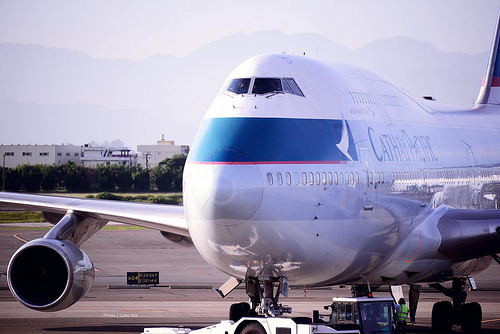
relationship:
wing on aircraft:
[0, 189, 187, 254] [1, 42, 496, 319]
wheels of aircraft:
[420, 296, 486, 329] [1, 42, 496, 319]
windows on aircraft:
[230, 73, 303, 96] [1, 42, 496, 319]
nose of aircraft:
[188, 163, 248, 202] [1, 42, 496, 319]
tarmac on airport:
[8, 308, 212, 317] [1, 42, 496, 319]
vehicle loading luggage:
[323, 291, 397, 332] [317, 303, 339, 322]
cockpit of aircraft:
[230, 73, 303, 96] [1, 42, 496, 319]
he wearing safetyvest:
[396, 296, 412, 331] [396, 304, 407, 320]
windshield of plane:
[230, 73, 303, 96] [1, 42, 496, 319]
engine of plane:
[4, 237, 94, 314] [1, 42, 496, 319]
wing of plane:
[0, 189, 187, 254] [1, 42, 496, 319]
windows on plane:
[342, 91, 407, 110] [1, 42, 496, 319]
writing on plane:
[368, 123, 440, 169] [1, 42, 496, 319]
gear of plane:
[231, 283, 295, 317] [1, 42, 496, 319]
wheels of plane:
[420, 296, 486, 329] [1, 42, 496, 319]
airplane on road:
[1, 42, 496, 319] [0, 222, 500, 333]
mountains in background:
[2, 34, 181, 88] [0, 1, 466, 56]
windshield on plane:
[230, 73, 303, 96] [1, 42, 496, 319]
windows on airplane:
[230, 73, 303, 96] [1, 42, 496, 319]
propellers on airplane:
[16, 238, 65, 305] [1, 42, 496, 319]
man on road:
[394, 298, 409, 332] [0, 222, 500, 333]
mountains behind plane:
[2, 34, 181, 88] [1, 42, 496, 319]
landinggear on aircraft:
[420, 296, 486, 329] [1, 42, 496, 319]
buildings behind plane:
[1, 143, 135, 157] [1, 42, 496, 319]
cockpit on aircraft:
[223, 80, 310, 103] [1, 42, 496, 319]